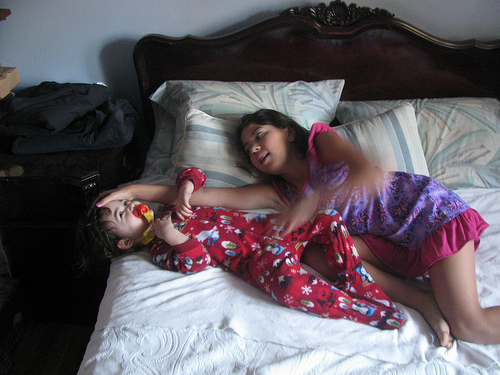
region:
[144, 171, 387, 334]
the onesie is red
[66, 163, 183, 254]
the baby with pacifier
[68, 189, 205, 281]
the baby with pacifier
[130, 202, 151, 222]
a red and yellow baby binky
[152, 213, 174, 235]
the hand of a baby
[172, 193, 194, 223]
the hand of a baby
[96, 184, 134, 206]
the hand of a girl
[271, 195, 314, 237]
the hand of a girl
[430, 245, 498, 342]
the leg of a girl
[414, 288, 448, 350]
the foot of a girl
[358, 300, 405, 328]
the foot of a baby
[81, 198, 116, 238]
the brown hair of a baby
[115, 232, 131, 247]
the ear of a child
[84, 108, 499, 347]
Girl and toddler laying on a bed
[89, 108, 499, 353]
Girl putting her hand on a boys head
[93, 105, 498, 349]
Girl wearing a purple and pink nightgown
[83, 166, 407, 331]
Boy wearing a red one piece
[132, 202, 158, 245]
Orange pacifier in a boys mouth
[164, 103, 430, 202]
White pillow with blue stripes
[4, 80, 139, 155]
Dark sheets folded on a nightstand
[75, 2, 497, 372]
Dark wood bed with white sheets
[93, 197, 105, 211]
Painted pink nail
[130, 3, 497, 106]
Dark mahogany headboard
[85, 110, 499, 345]
two kids laying in a bed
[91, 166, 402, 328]
a toddler in red footie pajamas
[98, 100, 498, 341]
girl holding the boy's head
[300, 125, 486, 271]
purple and pink pajamas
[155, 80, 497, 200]
pillows on a bed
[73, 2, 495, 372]
bed with a white bed spread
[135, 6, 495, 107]
dark brown headboard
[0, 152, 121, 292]
dark brown end table next to bed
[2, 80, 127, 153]
black clothing laying on end table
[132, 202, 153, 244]
red and yellow pacifier in the toddler's mouth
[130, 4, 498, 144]
a brown headboard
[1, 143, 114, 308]
part of a brown nightstand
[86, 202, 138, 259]
a boy's short cut hair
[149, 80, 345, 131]
part of a bed pillow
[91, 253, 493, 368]
part of a white sheet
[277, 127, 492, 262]
a girl's dress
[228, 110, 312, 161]
part of a girl's black hair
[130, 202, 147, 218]
a red pacifier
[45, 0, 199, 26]
part of a white wall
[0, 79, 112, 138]
a black sheet